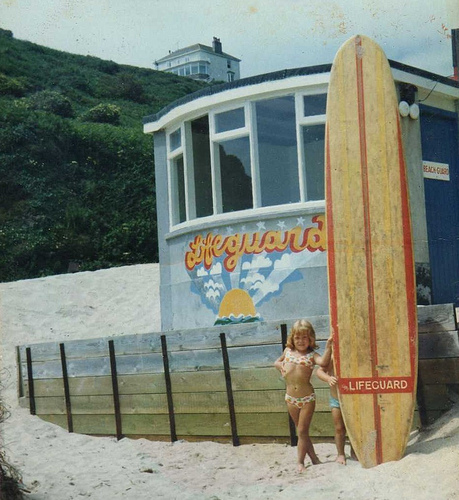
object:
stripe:
[317, 121, 341, 396]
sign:
[183, 212, 329, 374]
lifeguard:
[184, 212, 327, 270]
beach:
[0, 260, 458, 498]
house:
[142, 60, 459, 330]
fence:
[15, 303, 459, 449]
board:
[324, 32, 420, 475]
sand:
[0, 411, 457, 499]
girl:
[275, 320, 333, 470]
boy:
[315, 334, 356, 464]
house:
[154, 36, 241, 87]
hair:
[285, 321, 320, 354]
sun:
[217, 287, 257, 317]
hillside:
[0, 27, 204, 282]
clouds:
[271, 253, 297, 276]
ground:
[1, 261, 459, 499]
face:
[292, 334, 309, 350]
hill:
[0, 28, 206, 95]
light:
[399, 98, 411, 117]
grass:
[137, 467, 159, 476]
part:
[353, 260, 397, 315]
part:
[0, 27, 15, 69]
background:
[0, 0, 455, 195]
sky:
[243, 0, 459, 77]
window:
[211, 132, 256, 215]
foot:
[335, 450, 348, 465]